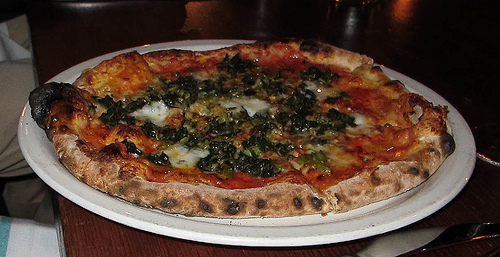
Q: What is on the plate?
A: A pizza.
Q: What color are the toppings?
A: Green.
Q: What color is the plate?
A: White.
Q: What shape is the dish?
A: Round.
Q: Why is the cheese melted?
A: Hot pizza.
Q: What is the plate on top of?
A: A table.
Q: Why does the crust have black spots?
A: Well done.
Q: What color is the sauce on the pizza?
A: Red.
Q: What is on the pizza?
A: Greens.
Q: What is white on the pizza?
A: Cheese.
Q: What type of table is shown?
A: Wooden.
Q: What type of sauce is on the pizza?
A: Tomato.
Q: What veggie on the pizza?
A: Spinach.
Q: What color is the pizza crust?
A: Brown.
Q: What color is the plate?
A: White.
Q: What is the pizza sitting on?
A: Table.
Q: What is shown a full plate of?
A: Pizza.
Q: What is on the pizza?
A: Cheese, tomatoes and greens.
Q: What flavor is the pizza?
A: Spinach and cheese.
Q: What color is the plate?
A: White.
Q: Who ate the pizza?
A: My friends.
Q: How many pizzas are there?
A: One.